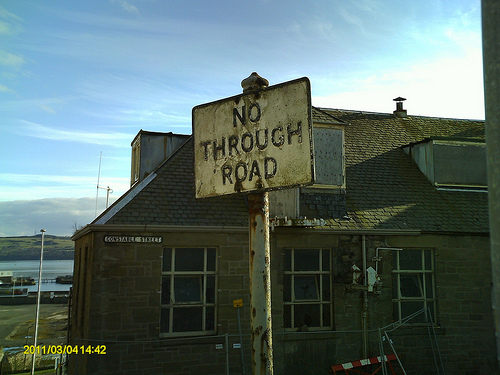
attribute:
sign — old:
[104, 233, 160, 244]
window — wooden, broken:
[162, 243, 215, 335]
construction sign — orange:
[332, 348, 402, 375]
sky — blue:
[4, 2, 484, 240]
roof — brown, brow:
[88, 104, 488, 228]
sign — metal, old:
[194, 76, 317, 200]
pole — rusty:
[247, 188, 273, 375]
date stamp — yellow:
[23, 340, 78, 357]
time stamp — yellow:
[81, 341, 107, 356]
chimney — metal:
[395, 96, 405, 109]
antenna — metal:
[76, 153, 117, 215]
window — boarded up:
[436, 144, 487, 185]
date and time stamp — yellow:
[24, 345, 108, 358]